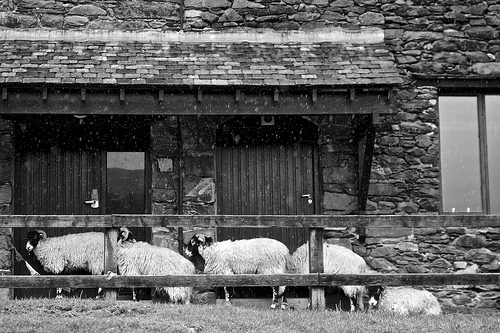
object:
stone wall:
[0, 0, 498, 76]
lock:
[302, 194, 313, 199]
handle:
[85, 200, 95, 203]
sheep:
[108, 226, 197, 304]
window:
[103, 150, 146, 214]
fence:
[0, 214, 500, 289]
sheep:
[288, 239, 371, 311]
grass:
[1, 299, 496, 331]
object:
[261, 115, 275, 126]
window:
[438, 77, 498, 218]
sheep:
[366, 283, 443, 316]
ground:
[6, 292, 498, 331]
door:
[20, 144, 148, 239]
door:
[219, 131, 319, 253]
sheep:
[186, 233, 295, 310]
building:
[0, 0, 498, 314]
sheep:
[25, 229, 116, 302]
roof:
[0, 29, 404, 114]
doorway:
[98, 144, 149, 239]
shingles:
[0, 42, 400, 87]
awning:
[3, 25, 408, 115]